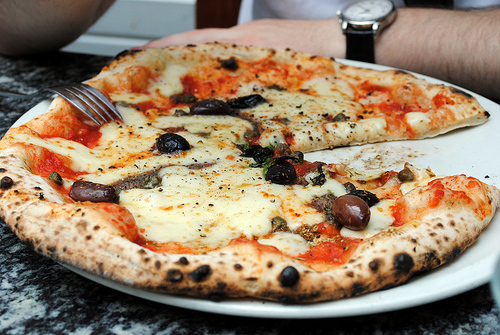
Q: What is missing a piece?
A: Pizza pie.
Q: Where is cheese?
A: On the pizza.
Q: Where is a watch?
A: On person's wrist.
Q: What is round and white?
A: Plate.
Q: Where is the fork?
A: On the pizza.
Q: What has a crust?
A: Pizza pie.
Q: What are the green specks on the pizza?
A: Seasoning.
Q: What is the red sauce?
A: Pizza sauce.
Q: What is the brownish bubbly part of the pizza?
A: Crust.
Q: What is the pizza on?
A: Plate.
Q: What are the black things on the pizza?
A: Olives.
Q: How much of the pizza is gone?
A: One slice.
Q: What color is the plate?
A: The plate is white.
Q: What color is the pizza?
A: The pizza is white and red and brown.